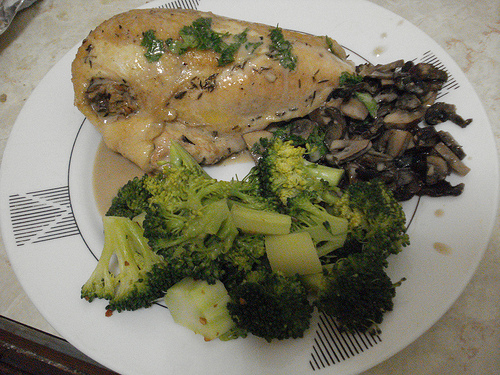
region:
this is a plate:
[8, 5, 480, 362]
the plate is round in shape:
[1, 11, 484, 366]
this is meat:
[68, 10, 260, 165]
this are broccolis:
[74, 161, 259, 313]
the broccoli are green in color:
[105, 215, 311, 332]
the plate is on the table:
[3, 10, 498, 370]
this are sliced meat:
[388, 54, 464, 196]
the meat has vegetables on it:
[179, 18, 295, 62]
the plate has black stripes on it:
[7, 190, 85, 238]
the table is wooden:
[1, 322, 113, 374]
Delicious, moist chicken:
[88, 18, 271, 122]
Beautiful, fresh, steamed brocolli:
[106, 167, 328, 317]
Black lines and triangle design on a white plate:
[9, 180, 81, 249]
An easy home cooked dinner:
[23, 15, 382, 374]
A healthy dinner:
[61, 12, 444, 349]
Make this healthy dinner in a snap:
[63, 24, 455, 349]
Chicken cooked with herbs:
[137, 7, 306, 89]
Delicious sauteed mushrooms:
[358, 67, 450, 181]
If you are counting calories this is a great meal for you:
[64, 17, 498, 289]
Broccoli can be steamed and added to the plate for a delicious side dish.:
[95, 170, 388, 336]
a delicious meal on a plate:
[12, 10, 489, 372]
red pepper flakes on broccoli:
[121, 253, 145, 274]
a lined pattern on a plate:
[16, 189, 79, 253]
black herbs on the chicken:
[187, 73, 234, 107]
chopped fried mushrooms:
[354, 87, 436, 187]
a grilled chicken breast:
[79, 0, 301, 171]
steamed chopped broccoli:
[165, 174, 354, 311]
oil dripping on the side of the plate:
[431, 209, 448, 260]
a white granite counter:
[454, 331, 491, 373]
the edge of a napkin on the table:
[5, 5, 25, 27]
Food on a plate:
[18, 15, 483, 313]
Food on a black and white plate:
[38, 29, 435, 309]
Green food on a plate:
[106, 160, 458, 320]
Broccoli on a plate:
[106, 165, 423, 338]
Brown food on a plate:
[324, 55, 467, 204]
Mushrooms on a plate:
[321, 78, 450, 194]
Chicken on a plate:
[67, 18, 345, 135]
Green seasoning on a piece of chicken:
[133, 14, 309, 76]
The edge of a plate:
[449, 203, 489, 322]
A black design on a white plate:
[8, 181, 82, 273]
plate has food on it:
[2, 12, 497, 374]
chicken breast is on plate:
[74, 11, 349, 162]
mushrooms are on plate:
[301, 52, 466, 204]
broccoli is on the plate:
[85, 141, 402, 336]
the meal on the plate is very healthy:
[53, 7, 477, 349]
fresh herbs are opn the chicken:
[136, 22, 296, 72]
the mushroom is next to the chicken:
[45, 6, 463, 197]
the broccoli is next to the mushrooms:
[86, 135, 406, 345]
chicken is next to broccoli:
[62, 5, 348, 175]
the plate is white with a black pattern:
[2, 3, 497, 373]